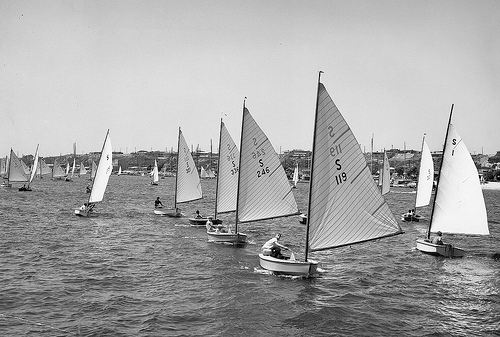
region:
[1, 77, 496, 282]
sailboats in the sea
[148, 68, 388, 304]
line of four sailboats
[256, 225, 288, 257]
man steering sailboat 119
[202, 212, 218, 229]
man steering sailboat 246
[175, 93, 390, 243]
four sails with stripes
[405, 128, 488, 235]
two all white sails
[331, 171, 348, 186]
black numbers on sail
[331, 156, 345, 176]
black letter on sail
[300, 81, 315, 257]
mast of sailboat 119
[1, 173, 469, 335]
water the sailboats are on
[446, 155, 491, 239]
Long white boat sail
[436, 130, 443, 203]
Long narrow black pole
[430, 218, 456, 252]
Person sitting on boat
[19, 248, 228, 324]
Waves on grey sea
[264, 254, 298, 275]
White and grey boat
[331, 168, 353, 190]
Boat sail number 119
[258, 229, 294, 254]
Person sitting dangerously on ship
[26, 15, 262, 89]
Grey clear cloudless sky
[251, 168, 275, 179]
Boat sail number 259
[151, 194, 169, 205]
Person in dark top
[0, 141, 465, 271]
Tons of boats in the water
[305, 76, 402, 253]
The mast of the boat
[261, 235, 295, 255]
A person steering the boat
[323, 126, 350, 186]
Writing on the sail of the boat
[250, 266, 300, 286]
Water splashing up around the boat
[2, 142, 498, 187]
The land in the distance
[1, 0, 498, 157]
A clear sky above the water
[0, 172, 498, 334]
A wavy body of water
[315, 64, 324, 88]
The tip of the sail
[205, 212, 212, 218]
A hat on a man's head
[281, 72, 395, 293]
sail boat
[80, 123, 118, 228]
sail boat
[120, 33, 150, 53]
white clouds in blue sky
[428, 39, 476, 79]
white clouds in blue sky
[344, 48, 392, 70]
white clouds in blue sky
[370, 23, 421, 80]
white clouds in blue sky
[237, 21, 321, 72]
white clouds in blue sky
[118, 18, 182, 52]
white clouds in blue sky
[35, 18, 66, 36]
white clouds in blue sky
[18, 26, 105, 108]
white clouds in blue sky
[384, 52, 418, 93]
white clouds in blue sky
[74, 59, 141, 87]
white clouds in blue sky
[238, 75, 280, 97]
white clouds in blue sky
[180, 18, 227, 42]
white clouds in blue sky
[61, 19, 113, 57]
white clouds in blue sky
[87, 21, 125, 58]
white clouds in blue sky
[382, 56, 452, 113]
white clouds in blue sky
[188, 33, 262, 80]
white clouds in blue sky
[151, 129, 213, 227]
boat